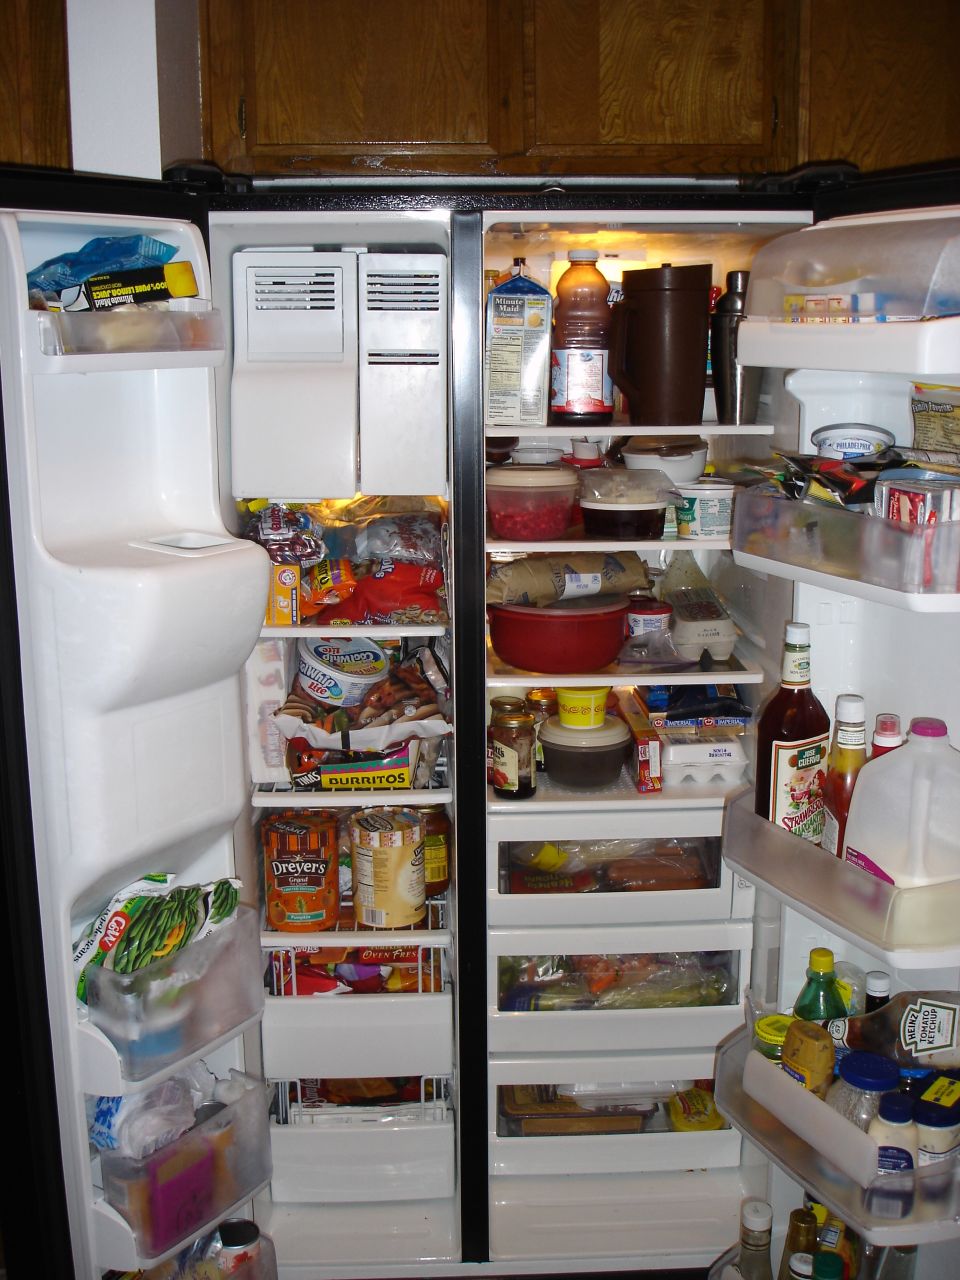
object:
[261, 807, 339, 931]
ice cream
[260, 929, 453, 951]
shelf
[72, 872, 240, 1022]
green beans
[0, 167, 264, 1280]
door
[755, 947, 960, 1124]
ketchup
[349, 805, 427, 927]
ice cream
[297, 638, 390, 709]
whip cream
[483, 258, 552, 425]
orange juice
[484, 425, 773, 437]
shelf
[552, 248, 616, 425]
juice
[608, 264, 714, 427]
juice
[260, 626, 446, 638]
shelf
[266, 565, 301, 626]
baking soda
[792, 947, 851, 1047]
lemon juice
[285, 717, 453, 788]
burritos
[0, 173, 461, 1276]
freezer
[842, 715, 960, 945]
milk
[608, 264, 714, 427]
brown pitcher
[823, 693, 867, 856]
ketchup bottle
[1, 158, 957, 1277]
fridge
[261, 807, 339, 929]
dreyer's ice-cream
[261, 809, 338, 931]
container